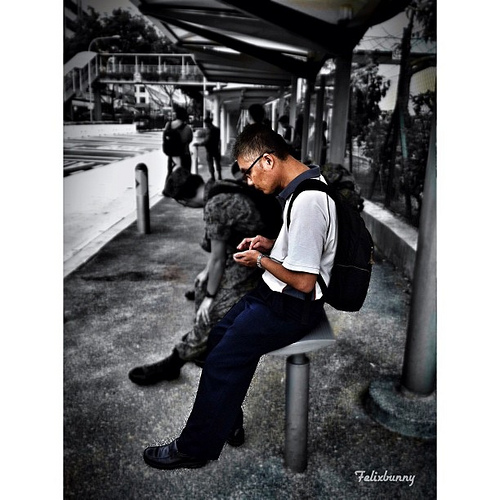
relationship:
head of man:
[224, 107, 309, 209] [157, 83, 423, 433]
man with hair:
[157, 83, 423, 433] [221, 107, 291, 150]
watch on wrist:
[248, 234, 281, 278] [181, 236, 276, 310]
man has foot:
[157, 83, 423, 433] [119, 399, 213, 479]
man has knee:
[157, 83, 423, 433] [179, 326, 278, 389]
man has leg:
[157, 83, 423, 433] [135, 331, 271, 480]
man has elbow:
[157, 83, 423, 433] [265, 251, 338, 318]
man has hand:
[157, 83, 423, 433] [199, 220, 264, 285]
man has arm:
[157, 83, 423, 433] [228, 239, 308, 295]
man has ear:
[157, 83, 423, 433] [254, 126, 302, 177]